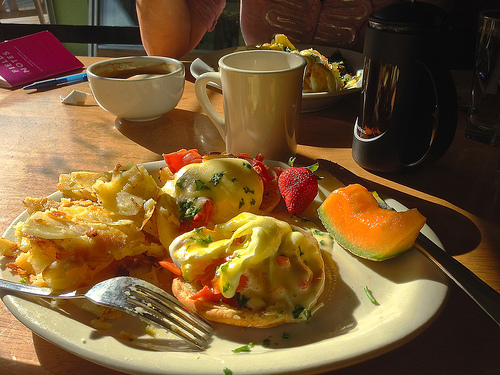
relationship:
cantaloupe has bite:
[321, 175, 427, 267] [346, 191, 405, 232]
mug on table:
[192, 45, 309, 163] [1, 52, 500, 373]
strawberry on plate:
[277, 156, 324, 219] [0, 153, 456, 375]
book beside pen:
[0, 29, 85, 89] [24, 73, 92, 96]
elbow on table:
[136, 1, 210, 61] [1, 52, 500, 373]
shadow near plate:
[275, 134, 487, 262] [0, 153, 456, 375]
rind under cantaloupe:
[315, 206, 415, 266] [321, 175, 427, 267]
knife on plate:
[320, 156, 499, 339] [0, 153, 456, 375]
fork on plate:
[3, 273, 219, 348] [0, 153, 456, 375]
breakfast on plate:
[1, 145, 433, 341] [0, 153, 456, 375]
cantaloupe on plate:
[321, 175, 427, 267] [0, 153, 456, 375]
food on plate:
[5, 146, 428, 333] [0, 153, 456, 375]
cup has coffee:
[81, 51, 190, 131] [99, 69, 174, 79]